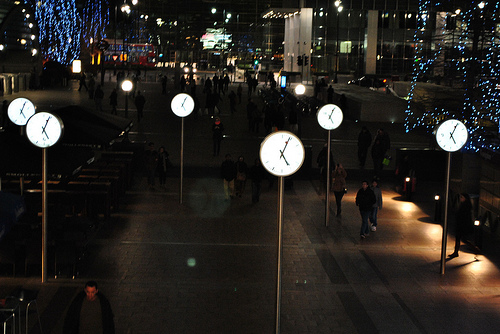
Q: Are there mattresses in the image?
A: No, there are no mattresses.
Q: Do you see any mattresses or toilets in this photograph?
A: No, there are no mattresses or toilets.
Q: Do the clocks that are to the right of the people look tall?
A: Yes, the clocks are tall.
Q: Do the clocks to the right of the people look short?
A: No, the clocks are tall.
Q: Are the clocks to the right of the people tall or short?
A: The clocks are tall.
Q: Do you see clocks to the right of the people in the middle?
A: Yes, there are clocks to the right of the people.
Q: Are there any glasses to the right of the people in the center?
A: No, there are clocks to the right of the people.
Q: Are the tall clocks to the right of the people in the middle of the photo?
A: Yes, the clocks are to the right of the people.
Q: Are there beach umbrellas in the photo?
A: No, there are no beach umbrellas.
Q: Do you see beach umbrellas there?
A: No, there are no beach umbrellas.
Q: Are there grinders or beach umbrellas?
A: No, there are no beach umbrellas or grinders.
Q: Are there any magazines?
A: No, there are no magazines.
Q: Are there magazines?
A: No, there are no magazines.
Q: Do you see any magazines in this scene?
A: No, there are no magazines.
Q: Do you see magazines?
A: No, there are no magazines.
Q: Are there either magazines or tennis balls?
A: No, there are no magazines or tennis balls.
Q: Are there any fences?
A: No, there are no fences.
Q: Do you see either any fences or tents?
A: No, there are no fences or tents.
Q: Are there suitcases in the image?
A: No, there are no suitcases.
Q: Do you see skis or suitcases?
A: No, there are no suitcases or skis.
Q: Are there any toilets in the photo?
A: No, there are no toilets.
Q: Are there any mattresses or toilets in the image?
A: No, there are no toilets or mattresses.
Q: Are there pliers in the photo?
A: No, there are no pliers.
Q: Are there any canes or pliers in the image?
A: No, there are no pliers or canes.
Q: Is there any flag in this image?
A: No, there are no flags.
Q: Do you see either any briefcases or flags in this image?
A: No, there are no flags or briefcases.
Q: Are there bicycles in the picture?
A: No, there are no bicycles.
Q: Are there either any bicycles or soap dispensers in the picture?
A: No, there are no bicycles or soap dispensers.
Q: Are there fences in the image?
A: No, there are no fences.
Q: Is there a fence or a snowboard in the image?
A: No, there are no fences or snowboards.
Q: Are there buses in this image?
A: Yes, there is a bus.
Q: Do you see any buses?
A: Yes, there is a bus.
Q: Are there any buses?
A: Yes, there is a bus.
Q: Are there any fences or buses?
A: Yes, there is a bus.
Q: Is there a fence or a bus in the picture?
A: Yes, there is a bus.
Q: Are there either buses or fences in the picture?
A: Yes, there is a bus.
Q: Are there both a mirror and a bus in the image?
A: No, there is a bus but no mirrors.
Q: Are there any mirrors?
A: No, there are no mirrors.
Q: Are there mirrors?
A: No, there are no mirrors.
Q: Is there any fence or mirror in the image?
A: No, there are no mirrors or fences.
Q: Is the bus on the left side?
A: Yes, the bus is on the left of the image.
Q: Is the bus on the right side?
A: No, the bus is on the left of the image.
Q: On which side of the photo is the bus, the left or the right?
A: The bus is on the left of the image.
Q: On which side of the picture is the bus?
A: The bus is on the left of the image.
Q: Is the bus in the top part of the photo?
A: Yes, the bus is in the top of the image.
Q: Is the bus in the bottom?
A: No, the bus is in the top of the image.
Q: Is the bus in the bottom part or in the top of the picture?
A: The bus is in the top of the image.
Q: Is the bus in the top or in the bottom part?
A: The bus is in the top of the image.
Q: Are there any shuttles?
A: No, there are no shuttles.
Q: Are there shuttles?
A: No, there are no shuttles.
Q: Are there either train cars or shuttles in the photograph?
A: No, there are no shuttles or train cars.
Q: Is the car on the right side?
A: Yes, the car is on the right of the image.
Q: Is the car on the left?
A: No, the car is on the right of the image.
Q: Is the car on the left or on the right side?
A: The car is on the right of the image.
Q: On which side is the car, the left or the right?
A: The car is on the right of the image.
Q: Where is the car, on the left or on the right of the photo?
A: The car is on the right of the image.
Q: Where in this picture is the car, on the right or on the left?
A: The car is on the right of the image.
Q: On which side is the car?
A: The car is on the right of the image.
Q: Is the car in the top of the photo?
A: Yes, the car is in the top of the image.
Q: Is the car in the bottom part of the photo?
A: No, the car is in the top of the image.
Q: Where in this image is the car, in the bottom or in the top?
A: The car is in the top of the image.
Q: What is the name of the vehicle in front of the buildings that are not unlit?
A: The vehicle is a car.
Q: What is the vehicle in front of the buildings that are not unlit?
A: The vehicle is a car.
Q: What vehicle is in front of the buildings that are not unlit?
A: The vehicle is a car.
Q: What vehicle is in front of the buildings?
A: The vehicle is a car.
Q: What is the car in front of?
A: The car is in front of the buildings.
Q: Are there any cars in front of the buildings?
A: Yes, there is a car in front of the buildings.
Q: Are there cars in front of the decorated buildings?
A: Yes, there is a car in front of the buildings.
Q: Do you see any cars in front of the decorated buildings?
A: Yes, there is a car in front of the buildings.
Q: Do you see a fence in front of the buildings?
A: No, there is a car in front of the buildings.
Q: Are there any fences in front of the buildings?
A: No, there is a car in front of the buildings.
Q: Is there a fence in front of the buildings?
A: No, there is a car in front of the buildings.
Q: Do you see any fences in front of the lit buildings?
A: No, there is a car in front of the buildings.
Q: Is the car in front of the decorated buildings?
A: Yes, the car is in front of the buildings.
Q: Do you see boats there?
A: No, there are no boats.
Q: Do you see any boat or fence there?
A: No, there are no boats or fences.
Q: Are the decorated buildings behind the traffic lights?
A: Yes, the buildings are behind the traffic lights.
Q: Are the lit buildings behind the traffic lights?
A: Yes, the buildings are behind the traffic lights.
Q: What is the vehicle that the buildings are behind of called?
A: The vehicle is a car.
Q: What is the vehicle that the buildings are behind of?
A: The vehicle is a car.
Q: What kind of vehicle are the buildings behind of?
A: The buildings are behind the car.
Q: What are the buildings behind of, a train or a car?
A: The buildings are behind a car.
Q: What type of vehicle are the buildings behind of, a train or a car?
A: The buildings are behind a car.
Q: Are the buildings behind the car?
A: Yes, the buildings are behind the car.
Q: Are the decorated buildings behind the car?
A: Yes, the buildings are behind the car.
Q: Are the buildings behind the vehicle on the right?
A: Yes, the buildings are behind the car.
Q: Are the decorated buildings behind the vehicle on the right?
A: Yes, the buildings are behind the car.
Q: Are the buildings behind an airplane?
A: No, the buildings are behind the car.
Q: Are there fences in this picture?
A: No, there are no fences.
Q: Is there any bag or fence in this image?
A: No, there are no fences or bags.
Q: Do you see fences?
A: No, there are no fences.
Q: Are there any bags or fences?
A: No, there are no fences or bags.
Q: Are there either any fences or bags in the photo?
A: No, there are no fences or bags.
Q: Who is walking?
A: The people are walking.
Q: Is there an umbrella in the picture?
A: No, there are no umbrellas.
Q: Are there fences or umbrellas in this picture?
A: No, there are no umbrellas or fences.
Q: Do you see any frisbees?
A: No, there are no frisbees.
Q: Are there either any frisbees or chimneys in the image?
A: No, there are no frisbees or chimneys.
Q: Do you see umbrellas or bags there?
A: No, there are no umbrellas or bags.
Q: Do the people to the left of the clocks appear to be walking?
A: Yes, the people are walking.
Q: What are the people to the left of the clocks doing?
A: The people are walking.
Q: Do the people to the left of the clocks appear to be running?
A: No, the people are walking.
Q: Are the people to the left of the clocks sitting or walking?
A: The people are walking.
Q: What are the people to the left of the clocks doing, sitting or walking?
A: The people are walking.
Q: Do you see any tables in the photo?
A: Yes, there is a table.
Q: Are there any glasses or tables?
A: Yes, there is a table.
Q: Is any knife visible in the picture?
A: No, there are no knives.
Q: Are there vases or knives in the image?
A: No, there are no knives or vases.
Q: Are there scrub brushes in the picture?
A: No, there are no scrub brushes.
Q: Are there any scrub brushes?
A: No, there are no scrub brushes.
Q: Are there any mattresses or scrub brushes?
A: No, there are no scrub brushes or mattresses.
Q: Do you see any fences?
A: No, there are no fences.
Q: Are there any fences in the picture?
A: No, there are no fences.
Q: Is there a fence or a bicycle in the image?
A: No, there are no fences or bicycles.